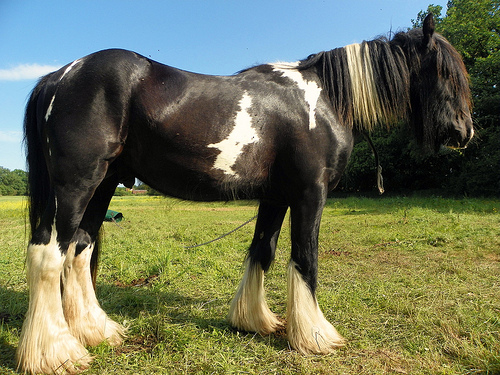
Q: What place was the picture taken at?
A: It was taken at the field.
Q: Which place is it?
A: It is a field.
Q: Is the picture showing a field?
A: Yes, it is showing a field.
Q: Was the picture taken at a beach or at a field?
A: It was taken at a field.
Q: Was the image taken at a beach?
A: No, the picture was taken in a field.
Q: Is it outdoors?
A: Yes, it is outdoors.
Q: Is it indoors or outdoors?
A: It is outdoors.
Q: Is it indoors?
A: No, it is outdoors.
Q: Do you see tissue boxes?
A: No, there are no tissue boxes.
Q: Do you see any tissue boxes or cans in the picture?
A: No, there are no tissue boxes or cans.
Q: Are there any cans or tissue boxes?
A: No, there are no tissue boxes or cans.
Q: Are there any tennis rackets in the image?
A: No, there are no tennis rackets.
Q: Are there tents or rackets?
A: No, there are no rackets or tents.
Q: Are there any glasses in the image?
A: No, there are no glasses.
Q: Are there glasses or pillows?
A: No, there are no glasses or pillows.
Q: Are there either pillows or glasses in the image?
A: No, there are no glasses or pillows.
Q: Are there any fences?
A: No, there are no fences.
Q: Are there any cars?
A: No, there are no cars.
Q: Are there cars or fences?
A: No, there are no cars or fences.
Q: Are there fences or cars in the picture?
A: No, there are no cars or fences.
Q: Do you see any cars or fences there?
A: No, there are no cars or fences.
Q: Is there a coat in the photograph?
A: Yes, there is a coat.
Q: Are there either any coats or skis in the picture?
A: Yes, there is a coat.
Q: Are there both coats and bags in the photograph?
A: No, there is a coat but no bags.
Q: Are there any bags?
A: No, there are no bags.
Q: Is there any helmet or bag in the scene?
A: No, there are no bags or helmets.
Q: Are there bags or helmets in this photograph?
A: No, there are no bags or helmets.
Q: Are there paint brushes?
A: No, there are no paint brushes.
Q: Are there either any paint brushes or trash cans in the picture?
A: No, there are no paint brushes or trash cans.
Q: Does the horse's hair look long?
A: Yes, the hair is long.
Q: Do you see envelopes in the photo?
A: No, there are no envelopes.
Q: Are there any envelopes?
A: No, there are no envelopes.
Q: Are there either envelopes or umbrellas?
A: No, there are no envelopes or umbrellas.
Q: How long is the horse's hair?
A: The hair is long.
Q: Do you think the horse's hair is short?
A: No, the hair is long.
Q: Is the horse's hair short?
A: No, the hair is long.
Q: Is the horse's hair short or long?
A: The hair is long.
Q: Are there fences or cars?
A: No, there are no fences or cars.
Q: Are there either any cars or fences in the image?
A: No, there are no fences or cars.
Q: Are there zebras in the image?
A: No, there are no zebras.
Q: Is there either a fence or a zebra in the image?
A: No, there are no zebras or fences.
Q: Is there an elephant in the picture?
A: No, there are no elephants.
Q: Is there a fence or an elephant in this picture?
A: No, there are no elephants or fences.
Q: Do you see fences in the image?
A: No, there are no fences.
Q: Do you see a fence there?
A: No, there are no fences.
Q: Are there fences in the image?
A: No, there are no fences.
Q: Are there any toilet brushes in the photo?
A: No, there are no toilet brushes.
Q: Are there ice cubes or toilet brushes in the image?
A: No, there are no toilet brushes or ice cubes.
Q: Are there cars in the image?
A: No, there are no cars.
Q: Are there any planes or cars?
A: No, there are no cars or planes.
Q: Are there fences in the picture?
A: No, there are no fences.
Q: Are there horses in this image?
A: Yes, there is a horse.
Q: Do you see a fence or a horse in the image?
A: Yes, there is a horse.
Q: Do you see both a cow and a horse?
A: No, there is a horse but no cows.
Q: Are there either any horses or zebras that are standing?
A: Yes, the horse is standing.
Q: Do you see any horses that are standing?
A: Yes, there is a horse that is standing.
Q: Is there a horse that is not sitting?
A: Yes, there is a horse that is standing.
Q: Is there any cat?
A: No, there are no cats.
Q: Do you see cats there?
A: No, there are no cats.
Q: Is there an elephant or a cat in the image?
A: No, there are no cats or elephants.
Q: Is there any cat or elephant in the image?
A: No, there are no cats or elephants.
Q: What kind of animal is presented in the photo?
A: The animal is a horse.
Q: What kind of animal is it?
A: The animal is a horse.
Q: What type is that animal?
A: This is a horse.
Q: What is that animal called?
A: This is a horse.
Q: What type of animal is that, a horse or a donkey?
A: This is a horse.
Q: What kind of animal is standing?
A: The animal is a horse.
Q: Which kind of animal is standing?
A: The animal is a horse.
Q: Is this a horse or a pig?
A: This is a horse.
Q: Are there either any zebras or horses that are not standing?
A: No, there is a horse but it is standing.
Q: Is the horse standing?
A: Yes, the horse is standing.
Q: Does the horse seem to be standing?
A: Yes, the horse is standing.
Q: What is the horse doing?
A: The horse is standing.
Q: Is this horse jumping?
A: No, the horse is standing.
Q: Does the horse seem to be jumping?
A: No, the horse is standing.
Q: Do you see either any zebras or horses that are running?
A: No, there is a horse but it is standing.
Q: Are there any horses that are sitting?
A: No, there is a horse but it is standing.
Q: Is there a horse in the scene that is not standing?
A: No, there is a horse but it is standing.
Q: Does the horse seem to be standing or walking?
A: The horse is standing.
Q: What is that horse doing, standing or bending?
A: The horse is standing.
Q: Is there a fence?
A: No, there are no fences.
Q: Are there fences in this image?
A: No, there are no fences.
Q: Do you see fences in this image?
A: No, there are no fences.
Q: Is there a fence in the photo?
A: No, there are no fences.